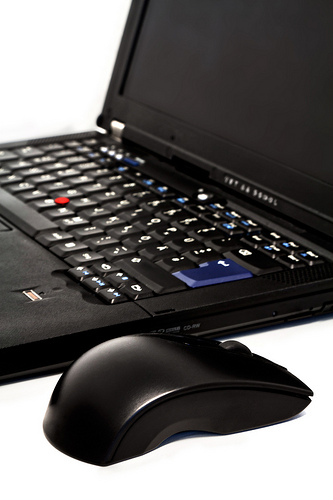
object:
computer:
[0, 0, 333, 391]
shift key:
[125, 253, 184, 293]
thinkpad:
[22, 8, 332, 340]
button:
[173, 259, 251, 288]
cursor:
[57, 196, 69, 207]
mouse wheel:
[219, 333, 254, 360]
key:
[0, 135, 326, 304]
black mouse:
[39, 331, 312, 465]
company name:
[221, 173, 280, 206]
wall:
[119, 54, 200, 73]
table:
[176, 436, 328, 487]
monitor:
[114, 3, 333, 192]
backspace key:
[225, 238, 283, 276]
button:
[292, 241, 318, 265]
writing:
[147, 320, 204, 332]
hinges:
[109, 118, 126, 142]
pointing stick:
[54, 191, 67, 207]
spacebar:
[0, 180, 60, 244]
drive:
[164, 285, 333, 339]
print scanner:
[20, 285, 43, 304]